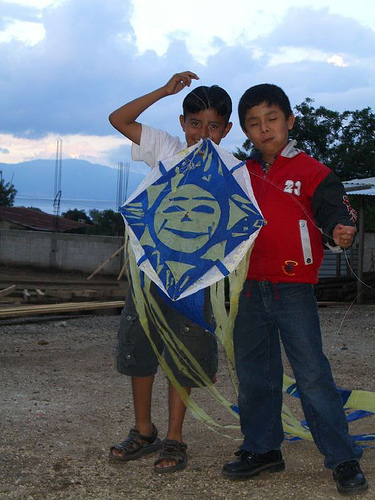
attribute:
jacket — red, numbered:
[238, 140, 360, 286]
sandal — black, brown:
[110, 426, 164, 466]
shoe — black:
[221, 445, 286, 480]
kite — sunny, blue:
[117, 135, 269, 303]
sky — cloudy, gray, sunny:
[0, 0, 374, 215]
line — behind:
[6, 193, 138, 214]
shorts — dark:
[115, 283, 218, 390]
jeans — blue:
[231, 277, 365, 469]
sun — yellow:
[136, 161, 252, 286]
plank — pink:
[0, 298, 127, 320]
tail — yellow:
[119, 233, 239, 441]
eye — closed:
[268, 112, 280, 123]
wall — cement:
[0, 229, 126, 279]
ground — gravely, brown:
[1, 303, 374, 499]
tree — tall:
[290, 97, 372, 181]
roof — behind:
[341, 175, 375, 199]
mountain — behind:
[2, 154, 150, 212]